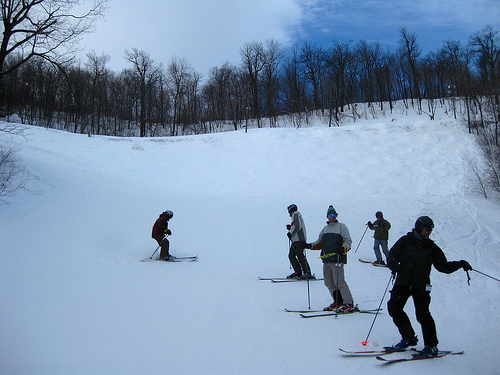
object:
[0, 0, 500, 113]
blue sky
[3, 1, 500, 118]
clouds